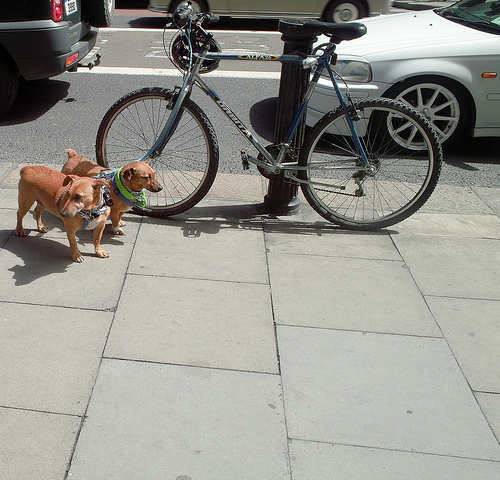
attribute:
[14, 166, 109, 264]
dog — small, brown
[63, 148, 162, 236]
dog — small, brown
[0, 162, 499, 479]
sidewalk — concrete, gray, blocks, white, tiles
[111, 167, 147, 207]
collar — green, blue, brightly colored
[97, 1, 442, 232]
bike — leaning, blue, parked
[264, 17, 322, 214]
post — black, short, metal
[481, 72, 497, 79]
reflector — orange, small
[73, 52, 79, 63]
light — red, tiny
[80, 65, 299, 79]
line — thick, white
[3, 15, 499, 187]
road — busy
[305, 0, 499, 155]
car — white, parked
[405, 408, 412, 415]
mark — tar, small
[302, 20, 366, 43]
seat — black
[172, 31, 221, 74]
helmet — black, hanging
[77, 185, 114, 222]
collar — brightly colored